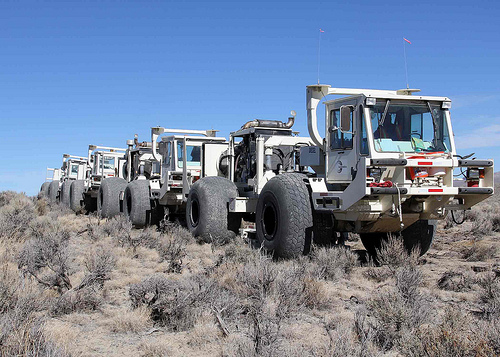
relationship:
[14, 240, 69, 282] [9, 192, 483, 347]
scrub brush on ground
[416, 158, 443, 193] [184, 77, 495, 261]
reflectors on front of truck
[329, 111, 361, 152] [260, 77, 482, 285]
mirror on truck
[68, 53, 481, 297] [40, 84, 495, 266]
convoy of trucks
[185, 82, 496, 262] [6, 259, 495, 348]
machine in desert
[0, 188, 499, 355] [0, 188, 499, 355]
desert filled with sagebrush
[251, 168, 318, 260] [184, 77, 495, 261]
tire on truck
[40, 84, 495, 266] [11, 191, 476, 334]
trucks driving across dirt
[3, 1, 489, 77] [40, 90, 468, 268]
skies above cars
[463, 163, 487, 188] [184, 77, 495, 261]
fire extinguisher outside truck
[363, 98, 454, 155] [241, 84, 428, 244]
window on truck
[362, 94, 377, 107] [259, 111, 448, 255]
headlight on truck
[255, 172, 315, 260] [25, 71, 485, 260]
tire on trucks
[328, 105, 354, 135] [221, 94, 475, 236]
mirror on truck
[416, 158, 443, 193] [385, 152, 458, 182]
reflectors on bar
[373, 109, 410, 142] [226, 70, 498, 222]
man inside of truck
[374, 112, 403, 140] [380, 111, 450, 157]
man wearing vest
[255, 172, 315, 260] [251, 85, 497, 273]
tire on vehicle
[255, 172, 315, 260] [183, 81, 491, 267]
tire on vehicle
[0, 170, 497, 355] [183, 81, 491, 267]
ground by vehicle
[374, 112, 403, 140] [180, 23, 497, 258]
man in truck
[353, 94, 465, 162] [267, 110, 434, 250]
window in truck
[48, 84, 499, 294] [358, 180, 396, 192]
trucks has headlight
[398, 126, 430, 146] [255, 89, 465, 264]
steering has truck